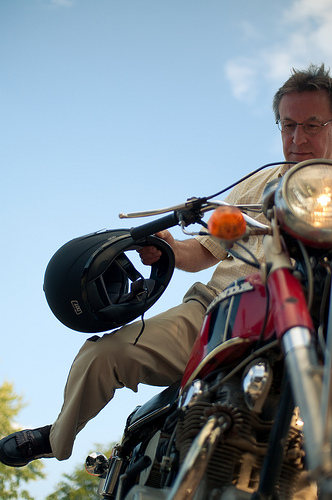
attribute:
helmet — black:
[43, 223, 176, 334]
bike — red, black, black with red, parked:
[85, 158, 332, 499]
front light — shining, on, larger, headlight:
[272, 156, 330, 249]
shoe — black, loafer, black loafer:
[1, 427, 60, 465]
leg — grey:
[46, 303, 209, 457]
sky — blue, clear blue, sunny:
[4, 1, 331, 500]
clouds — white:
[223, 4, 331, 109]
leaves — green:
[1, 378, 123, 500]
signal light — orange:
[206, 211, 247, 243]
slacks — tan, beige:
[49, 282, 225, 460]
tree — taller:
[1, 388, 48, 499]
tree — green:
[42, 441, 118, 500]